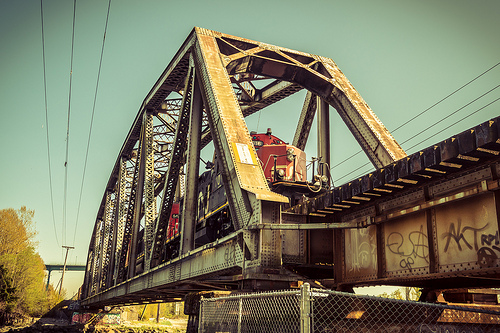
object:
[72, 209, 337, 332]
bridge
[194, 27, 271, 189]
wall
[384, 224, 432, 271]
words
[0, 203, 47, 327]
trees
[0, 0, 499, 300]
sky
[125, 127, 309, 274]
train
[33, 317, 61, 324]
road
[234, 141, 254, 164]
paper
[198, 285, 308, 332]
fence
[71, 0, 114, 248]
wire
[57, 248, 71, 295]
pole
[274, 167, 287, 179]
light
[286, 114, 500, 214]
tracks